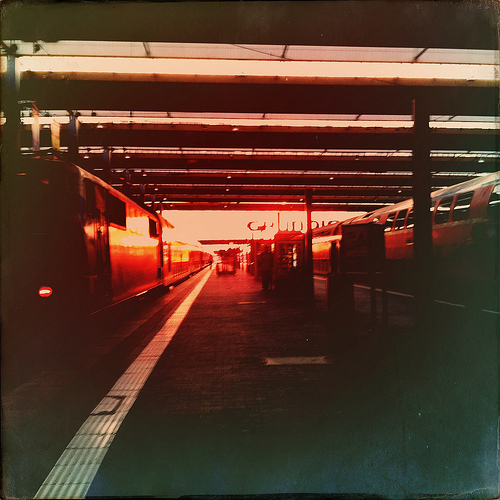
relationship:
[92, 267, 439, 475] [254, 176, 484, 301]
platform between train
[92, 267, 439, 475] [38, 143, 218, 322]
platform between train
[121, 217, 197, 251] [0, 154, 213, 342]
sun on subway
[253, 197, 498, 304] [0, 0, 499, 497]
train in station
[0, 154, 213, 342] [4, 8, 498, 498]
subway in station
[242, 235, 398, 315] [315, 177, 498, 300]
people front train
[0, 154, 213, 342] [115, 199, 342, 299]
subway in dusk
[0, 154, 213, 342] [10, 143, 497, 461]
subway in stop